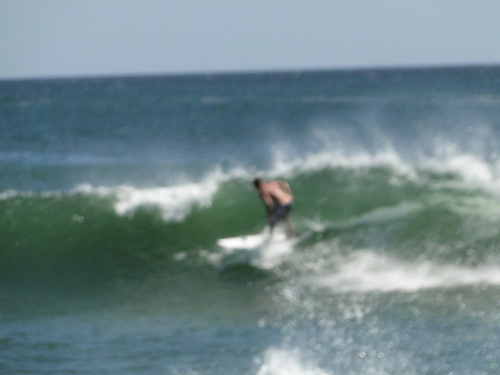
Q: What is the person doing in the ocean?
A: Surfing.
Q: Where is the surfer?
A: In the ocean.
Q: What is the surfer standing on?
A: A surfboard.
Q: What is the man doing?
A: Surfing.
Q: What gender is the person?
A: Male.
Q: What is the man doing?
A: Surfing.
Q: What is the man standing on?
A: Surfboard.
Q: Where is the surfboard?
A: In the water.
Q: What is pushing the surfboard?
A: Waves.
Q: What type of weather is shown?
A: Clear.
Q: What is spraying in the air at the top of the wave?
A: Water.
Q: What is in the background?
A: Water.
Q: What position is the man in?
A: Bent.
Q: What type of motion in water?
A: Waves.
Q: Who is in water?
A: The man.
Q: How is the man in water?
A: Surfing.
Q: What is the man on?
A: Surfboard.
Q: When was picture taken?
A: Daytime.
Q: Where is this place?
A: A beach.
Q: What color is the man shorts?
A: Black.